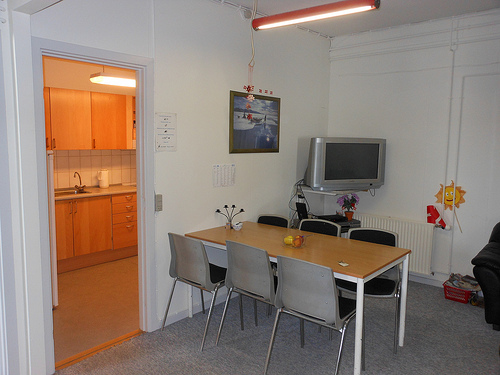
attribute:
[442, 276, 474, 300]
baskets — red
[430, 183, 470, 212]
sun — homemade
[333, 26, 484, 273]
wall — white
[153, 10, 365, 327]
wall — white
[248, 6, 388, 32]
light fixture — brown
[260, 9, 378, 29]
light — flourescent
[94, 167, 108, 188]
pitcher — white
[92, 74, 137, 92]
light fixture — fluorescent